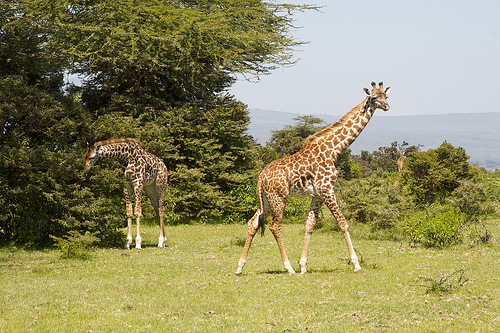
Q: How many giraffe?
A: 2.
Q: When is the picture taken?
A: Daytime.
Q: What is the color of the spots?
A: Brown.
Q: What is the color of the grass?
A: Green.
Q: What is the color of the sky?
A: Blue.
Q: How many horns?
A: Two.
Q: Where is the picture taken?
A: At the zoo.